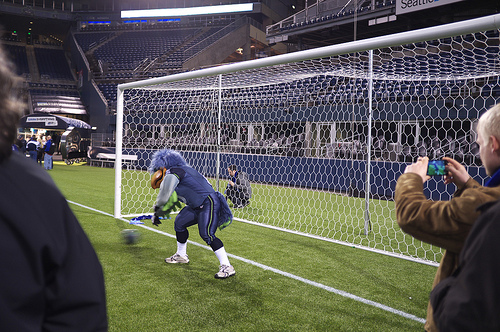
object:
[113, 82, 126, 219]
pole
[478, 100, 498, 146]
hair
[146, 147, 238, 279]
mascot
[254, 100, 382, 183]
mesh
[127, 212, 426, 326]
line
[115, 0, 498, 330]
goal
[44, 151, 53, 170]
jeans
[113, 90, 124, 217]
fence pole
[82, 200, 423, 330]
grass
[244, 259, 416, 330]
stripe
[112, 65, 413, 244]
bars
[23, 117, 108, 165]
seats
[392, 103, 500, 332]
man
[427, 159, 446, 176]
cellphone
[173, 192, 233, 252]
pants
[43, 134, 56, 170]
man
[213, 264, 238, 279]
tennis shoe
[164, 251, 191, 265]
tennis shoe